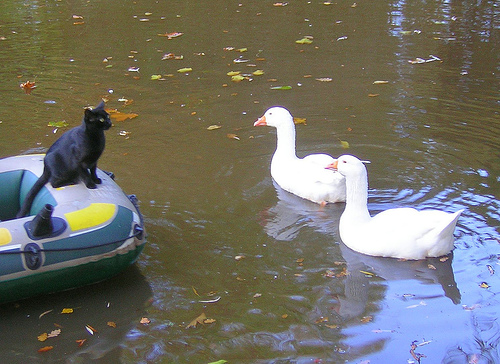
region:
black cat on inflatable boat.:
[40, 101, 110, 186]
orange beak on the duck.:
[252, 111, 262, 123]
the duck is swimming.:
[322, 151, 462, 257]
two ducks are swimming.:
[250, 105, 460, 260]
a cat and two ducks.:
[40, 101, 460, 256]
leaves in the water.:
[146, 70, 261, 80]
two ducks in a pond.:
[250, 101, 462, 257]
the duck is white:
[325, 152, 463, 257]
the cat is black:
[24, 103, 112, 215]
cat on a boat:
[0, 101, 145, 300]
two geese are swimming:
[252, 105, 463, 261]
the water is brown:
[2, 1, 498, 362]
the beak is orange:
[252, 115, 263, 125]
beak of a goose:
[325, 159, 337, 169]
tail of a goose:
[446, 209, 461, 226]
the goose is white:
[325, 153, 462, 257]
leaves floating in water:
[127, 29, 267, 82]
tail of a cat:
[24, 170, 44, 215]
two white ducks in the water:
[252, 106, 465, 261]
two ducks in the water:
[252, 105, 464, 263]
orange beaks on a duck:
[252, 113, 268, 130]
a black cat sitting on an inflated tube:
[17, 100, 114, 215]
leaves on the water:
[115, 11, 252, 124]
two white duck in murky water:
[222, 90, 487, 271]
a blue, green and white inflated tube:
[1, 153, 149, 304]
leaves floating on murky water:
[33, 304, 247, 362]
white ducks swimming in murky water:
[224, 83, 490, 273]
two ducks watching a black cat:
[252, 105, 466, 260]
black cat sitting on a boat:
[20, 99, 120, 189]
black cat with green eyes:
[77, 102, 116, 135]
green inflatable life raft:
[0, 147, 139, 311]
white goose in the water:
[325, 149, 464, 258]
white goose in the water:
[251, 98, 354, 205]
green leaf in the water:
[295, 35, 308, 45]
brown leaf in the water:
[186, 311, 208, 330]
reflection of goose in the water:
[257, 173, 336, 239]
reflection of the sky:
[327, 188, 497, 360]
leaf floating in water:
[356, 309, 375, 329]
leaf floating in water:
[182, 309, 208, 332]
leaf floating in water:
[136, 313, 155, 330]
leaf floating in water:
[81, 320, 101, 340]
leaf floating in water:
[73, 335, 88, 350]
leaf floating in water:
[33, 306, 53, 323]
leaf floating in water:
[44, 326, 63, 340]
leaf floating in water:
[34, 328, 49, 345]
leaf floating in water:
[34, 338, 54, 353]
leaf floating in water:
[110, 108, 142, 127]